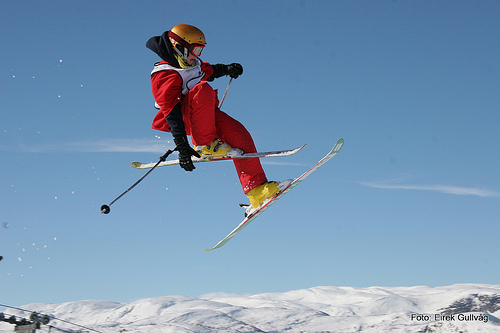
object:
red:
[242, 164, 260, 184]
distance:
[0, 67, 483, 227]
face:
[189, 47, 204, 65]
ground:
[2, 200, 494, 321]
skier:
[149, 23, 295, 215]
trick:
[80, 15, 360, 257]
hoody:
[142, 31, 222, 138]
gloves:
[228, 63, 244, 79]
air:
[7, 3, 500, 323]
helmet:
[167, 24, 207, 69]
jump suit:
[144, 56, 273, 196]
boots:
[246, 179, 293, 209]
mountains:
[1, 281, 499, 332]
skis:
[208, 140, 344, 252]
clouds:
[346, 170, 493, 208]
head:
[167, 24, 206, 65]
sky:
[3, 1, 497, 282]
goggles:
[183, 44, 205, 57]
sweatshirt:
[150, 56, 224, 134]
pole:
[97, 145, 180, 214]